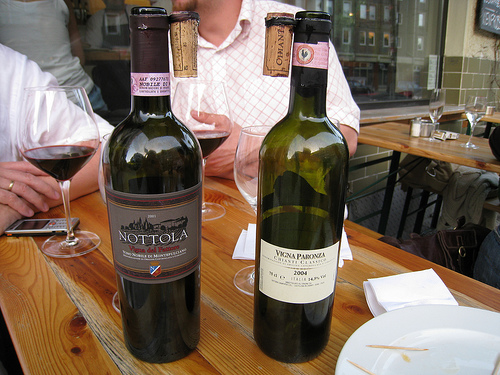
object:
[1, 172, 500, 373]
table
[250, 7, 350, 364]
bottle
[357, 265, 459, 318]
napkin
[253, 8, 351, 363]
champagne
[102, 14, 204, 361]
wine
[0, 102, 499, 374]
bar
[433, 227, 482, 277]
bag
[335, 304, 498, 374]
white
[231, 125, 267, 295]
glass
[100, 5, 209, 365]
bottle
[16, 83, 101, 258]
clear glass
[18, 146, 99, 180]
red wine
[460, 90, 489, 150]
clear glass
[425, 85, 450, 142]
green leaves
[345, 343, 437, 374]
toothpicks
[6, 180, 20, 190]
ring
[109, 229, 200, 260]
writing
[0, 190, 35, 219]
finger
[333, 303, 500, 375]
plate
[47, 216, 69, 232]
button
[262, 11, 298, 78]
cork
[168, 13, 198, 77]
cork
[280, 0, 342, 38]
top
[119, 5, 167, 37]
top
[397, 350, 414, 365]
crumbs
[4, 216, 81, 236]
cell phone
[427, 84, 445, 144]
glass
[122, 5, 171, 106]
foil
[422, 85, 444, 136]
wine glass